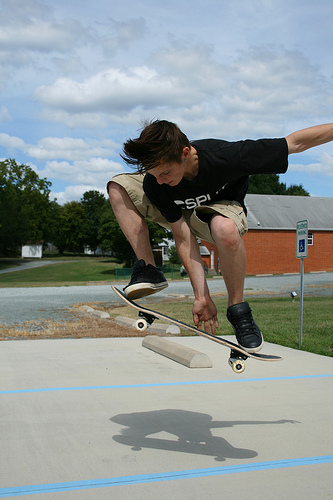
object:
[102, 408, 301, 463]
shadow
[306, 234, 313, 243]
window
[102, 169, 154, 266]
leg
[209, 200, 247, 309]
leg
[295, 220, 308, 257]
sign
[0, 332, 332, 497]
parking lot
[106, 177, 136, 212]
knee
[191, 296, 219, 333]
hand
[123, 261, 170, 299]
shoe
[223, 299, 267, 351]
shoe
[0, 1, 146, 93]
cloud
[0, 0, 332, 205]
sky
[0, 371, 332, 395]
blue stripe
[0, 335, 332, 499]
concrete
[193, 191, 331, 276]
building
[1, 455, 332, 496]
stripe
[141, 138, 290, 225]
shirt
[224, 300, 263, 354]
feet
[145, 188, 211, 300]
arm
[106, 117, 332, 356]
boy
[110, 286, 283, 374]
skateboard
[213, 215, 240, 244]
knee